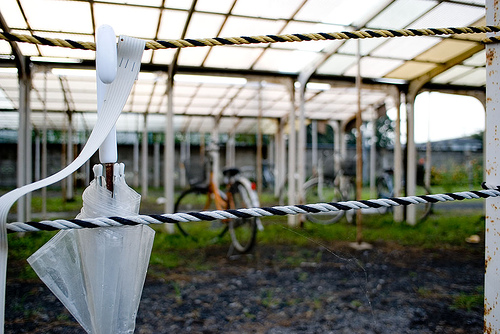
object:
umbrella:
[25, 24, 155, 333]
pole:
[164, 64, 176, 234]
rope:
[0, 24, 499, 50]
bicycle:
[173, 157, 264, 257]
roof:
[0, 0, 486, 136]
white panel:
[366, 0, 441, 30]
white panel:
[251, 45, 317, 74]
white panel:
[93, 2, 160, 42]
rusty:
[484, 0, 500, 334]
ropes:
[0, 25, 500, 234]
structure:
[0, 0, 499, 246]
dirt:
[5, 244, 485, 334]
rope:
[5, 182, 500, 235]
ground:
[3, 200, 484, 334]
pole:
[484, 1, 500, 334]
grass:
[8, 184, 485, 284]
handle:
[94, 25, 119, 163]